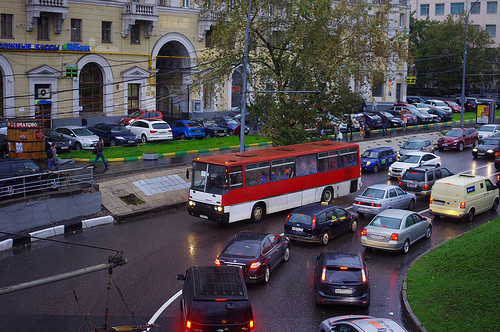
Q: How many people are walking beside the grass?
A: 1.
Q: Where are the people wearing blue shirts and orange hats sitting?
A: On the bus.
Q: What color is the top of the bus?
A: Red.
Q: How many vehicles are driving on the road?
A: 16.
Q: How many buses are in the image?
A: 1.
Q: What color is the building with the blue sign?
A: Yellow.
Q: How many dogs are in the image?
A: 0.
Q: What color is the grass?
A: Green.